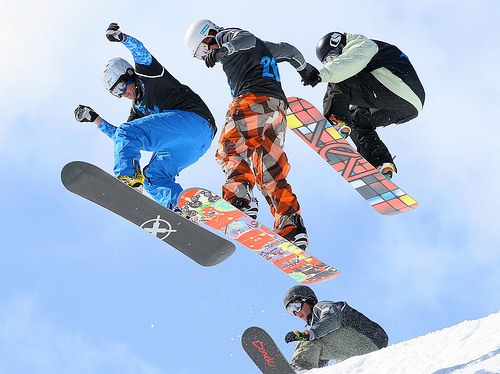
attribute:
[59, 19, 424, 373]
skiers — jumping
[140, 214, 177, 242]
image — white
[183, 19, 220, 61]
helmet — white, gray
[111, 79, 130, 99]
googles — ski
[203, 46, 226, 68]
glove — black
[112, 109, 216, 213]
pants — blue, ski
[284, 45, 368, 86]
hands — holding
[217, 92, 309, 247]
ski pants — checker patterned, chekered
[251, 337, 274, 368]
writing — red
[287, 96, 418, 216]
snowboard — checkered, red, yellow, blue, black, white, multicolored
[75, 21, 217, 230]
man — jumping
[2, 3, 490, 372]
sky — blue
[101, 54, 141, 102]
head — man's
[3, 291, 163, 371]
clouds — white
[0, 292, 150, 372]
clouds — white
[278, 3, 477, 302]
clouds — white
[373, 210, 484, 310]
clouds — white